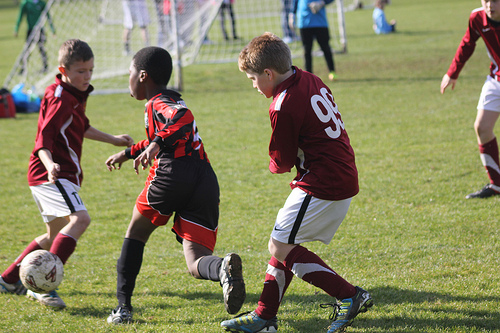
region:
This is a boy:
[233, 19, 388, 331]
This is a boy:
[100, 38, 253, 318]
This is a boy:
[3, 27, 111, 331]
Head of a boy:
[109, 46, 189, 110]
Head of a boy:
[48, 31, 104, 93]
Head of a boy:
[231, 28, 303, 99]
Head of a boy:
[113, 39, 193, 114]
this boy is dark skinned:
[104, 44, 248, 324]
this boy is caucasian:
[218, 28, 378, 331]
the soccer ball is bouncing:
[18, 245, 71, 296]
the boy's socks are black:
[114, 233, 226, 313]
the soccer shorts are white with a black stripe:
[262, 180, 357, 251]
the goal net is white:
[3, 2, 351, 94]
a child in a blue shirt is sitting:
[367, 1, 398, 38]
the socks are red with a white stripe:
[247, 245, 354, 317]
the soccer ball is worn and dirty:
[15, 248, 67, 293]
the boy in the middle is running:
[100, 42, 247, 330]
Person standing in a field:
[443, 4, 492, 230]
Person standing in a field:
[238, 35, 413, 316]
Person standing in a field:
[103, 43, 228, 312]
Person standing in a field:
[36, 39, 106, 323]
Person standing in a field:
[293, 1, 362, 84]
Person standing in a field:
[13, 5, 56, 72]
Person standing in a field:
[115, 6, 174, 53]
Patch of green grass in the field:
[30, 307, 86, 327]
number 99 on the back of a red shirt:
[309, 80, 348, 143]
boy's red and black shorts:
[130, 153, 227, 246]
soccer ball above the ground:
[19, 244, 71, 299]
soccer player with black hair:
[98, 35, 249, 322]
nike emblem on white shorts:
[271, 223, 287, 237]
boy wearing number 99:
[216, 28, 386, 332]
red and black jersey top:
[122, 86, 213, 166]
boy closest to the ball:
[4, 32, 136, 318]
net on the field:
[1, 0, 355, 105]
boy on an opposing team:
[103, 37, 251, 325]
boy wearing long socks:
[232, 31, 378, 326]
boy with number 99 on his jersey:
[224, 34, 384, 329]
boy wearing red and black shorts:
[96, 27, 246, 313]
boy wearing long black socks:
[87, 35, 247, 323]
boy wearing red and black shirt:
[88, 39, 243, 314]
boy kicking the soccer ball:
[10, 26, 95, 313]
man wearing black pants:
[288, 3, 358, 93]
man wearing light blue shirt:
[290, 0, 345, 72]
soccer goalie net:
[51, 0, 344, 79]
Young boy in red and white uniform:
[219, 32, 375, 332]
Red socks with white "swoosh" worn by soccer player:
[255, 244, 359, 318]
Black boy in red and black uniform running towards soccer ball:
[106, 46, 248, 325]